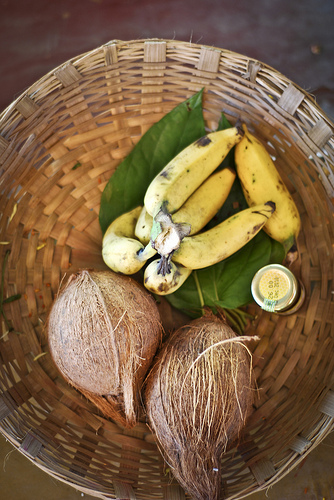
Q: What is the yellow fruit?
A: Banana.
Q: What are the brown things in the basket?
A: Coconuts.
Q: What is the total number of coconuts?
A: 2.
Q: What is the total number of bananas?
A: 7.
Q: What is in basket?
A: Bananas.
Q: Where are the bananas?
A: Next to coconuts.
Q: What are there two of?
A: Coconuts.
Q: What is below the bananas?
A: Green leaves.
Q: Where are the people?
A: No people in photo.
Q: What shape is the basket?
A: Round.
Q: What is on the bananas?
A: Brown spots.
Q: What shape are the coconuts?
A: Round.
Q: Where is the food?
A: In a basket.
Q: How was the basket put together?
A: Woven.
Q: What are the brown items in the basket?
A: Coconuts.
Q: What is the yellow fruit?
A: Banana.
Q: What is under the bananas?
A: Leaves.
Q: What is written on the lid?
A: Numbers.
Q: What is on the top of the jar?
A: A lid.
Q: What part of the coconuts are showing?
A: The husk.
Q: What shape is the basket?
A: Round.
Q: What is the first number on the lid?
A: 26.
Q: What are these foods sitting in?
A: Basket.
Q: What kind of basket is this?
A: Wicker weave.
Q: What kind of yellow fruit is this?
A: Banana.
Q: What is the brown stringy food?
A: Coconut.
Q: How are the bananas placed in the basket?
A: On top of green leaves.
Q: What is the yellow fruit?
A: Banana.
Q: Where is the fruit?
A: In a basket.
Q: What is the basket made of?
A: Woven material.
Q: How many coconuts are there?
A: Two.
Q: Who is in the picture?
A: No one.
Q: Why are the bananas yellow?
A: They are ripe.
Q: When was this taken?
A: During the day.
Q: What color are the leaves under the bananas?
A: Green.